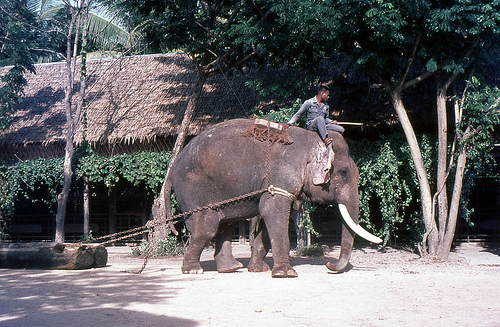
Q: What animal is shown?
A: Elephant.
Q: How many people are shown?
A: One.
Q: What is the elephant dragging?
A: Logs.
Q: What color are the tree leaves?
A: Green.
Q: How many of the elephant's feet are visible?
A: Four.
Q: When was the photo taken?
A: Daytime.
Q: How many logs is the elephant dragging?
A: Two.